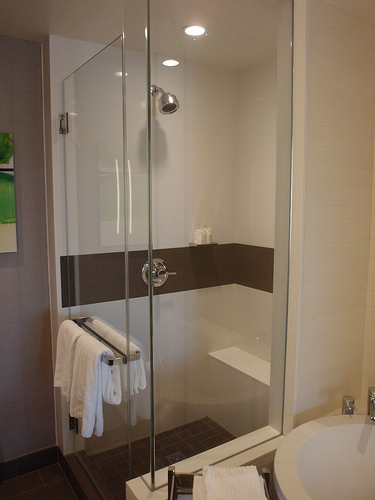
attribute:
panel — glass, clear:
[60, 29, 125, 480]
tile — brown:
[89, 415, 236, 497]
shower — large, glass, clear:
[54, 1, 288, 500]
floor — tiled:
[1, 462, 75, 499]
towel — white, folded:
[189, 462, 266, 499]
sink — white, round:
[271, 411, 373, 499]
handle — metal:
[73, 318, 118, 369]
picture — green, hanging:
[1, 133, 15, 251]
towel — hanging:
[70, 330, 120, 439]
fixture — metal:
[150, 82, 179, 115]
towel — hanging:
[48, 316, 82, 398]